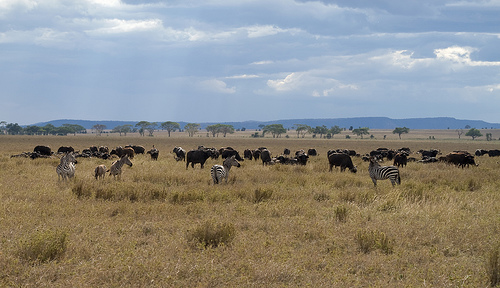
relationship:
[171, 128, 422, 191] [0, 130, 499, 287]
animals on a field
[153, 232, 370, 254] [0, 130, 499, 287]
grass on  a field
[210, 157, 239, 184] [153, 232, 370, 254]
animals in grass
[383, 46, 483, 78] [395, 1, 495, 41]
cloud in sky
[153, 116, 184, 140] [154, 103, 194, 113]
tree in distance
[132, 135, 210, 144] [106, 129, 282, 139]
brown grass of a plain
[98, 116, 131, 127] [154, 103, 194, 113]
mountains in distance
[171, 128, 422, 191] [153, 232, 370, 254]
animals grazing in grass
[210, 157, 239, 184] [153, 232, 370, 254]
animals grazing in grass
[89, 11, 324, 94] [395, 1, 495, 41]
clouds covering sky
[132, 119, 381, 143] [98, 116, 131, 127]
trees in front of mountains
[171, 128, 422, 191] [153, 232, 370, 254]
animals are standing in grass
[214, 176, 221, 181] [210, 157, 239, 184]
tail of animals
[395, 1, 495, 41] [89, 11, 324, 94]
sky covered with clouds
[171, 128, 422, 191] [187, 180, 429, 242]
animals in a field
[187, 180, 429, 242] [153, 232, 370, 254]
field full of grass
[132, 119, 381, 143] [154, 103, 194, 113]
trees in distance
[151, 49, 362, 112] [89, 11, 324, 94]
light shining through clouds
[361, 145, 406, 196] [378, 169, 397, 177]
zebra has black white stripes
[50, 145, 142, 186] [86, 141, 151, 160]
zebras and buffalos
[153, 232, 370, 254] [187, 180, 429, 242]
grass in field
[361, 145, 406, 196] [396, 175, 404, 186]
zebra has a tail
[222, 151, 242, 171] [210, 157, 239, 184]
head of a animals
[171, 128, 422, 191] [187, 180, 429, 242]
animals in field